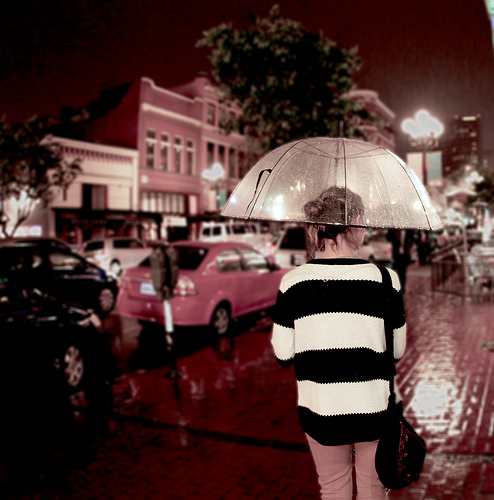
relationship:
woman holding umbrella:
[268, 187, 411, 495] [216, 122, 450, 240]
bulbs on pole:
[200, 162, 228, 182] [212, 182, 222, 217]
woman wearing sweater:
[268, 187, 411, 495] [270, 256, 409, 444]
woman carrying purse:
[268, 187, 411, 495] [372, 402, 430, 493]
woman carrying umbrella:
[268, 187, 411, 495] [216, 122, 450, 240]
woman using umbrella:
[268, 187, 411, 495] [216, 122, 450, 240]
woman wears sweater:
[268, 187, 411, 495] [270, 256, 409, 444]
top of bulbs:
[197, 158, 226, 185] [198, 160, 231, 185]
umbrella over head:
[216, 122, 450, 240] [305, 187, 369, 260]